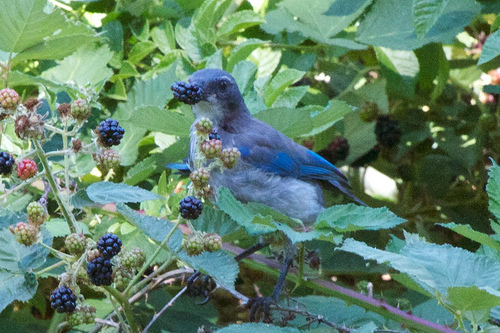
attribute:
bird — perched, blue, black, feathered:
[175, 71, 380, 313]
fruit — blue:
[51, 232, 129, 303]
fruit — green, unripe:
[189, 120, 242, 186]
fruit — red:
[17, 153, 39, 178]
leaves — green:
[73, 2, 480, 120]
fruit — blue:
[174, 80, 203, 108]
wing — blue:
[284, 146, 375, 208]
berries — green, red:
[187, 231, 222, 256]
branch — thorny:
[34, 144, 101, 238]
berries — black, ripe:
[18, 196, 138, 287]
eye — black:
[216, 75, 239, 94]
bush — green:
[9, 16, 486, 317]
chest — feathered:
[219, 155, 311, 215]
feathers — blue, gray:
[242, 145, 322, 189]